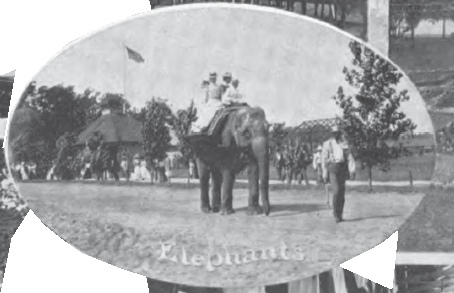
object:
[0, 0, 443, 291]
photo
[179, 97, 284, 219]
elephant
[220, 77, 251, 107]
people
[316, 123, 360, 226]
man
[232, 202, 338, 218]
shadow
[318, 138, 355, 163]
white shirt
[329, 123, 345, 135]
hat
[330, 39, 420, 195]
tree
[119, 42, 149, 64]
flag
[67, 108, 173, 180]
building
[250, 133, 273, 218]
trunk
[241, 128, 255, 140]
eyes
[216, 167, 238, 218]
legs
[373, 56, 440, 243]
right of photo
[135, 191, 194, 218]
walkway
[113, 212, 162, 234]
grass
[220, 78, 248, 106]
woman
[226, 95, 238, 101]
white dress